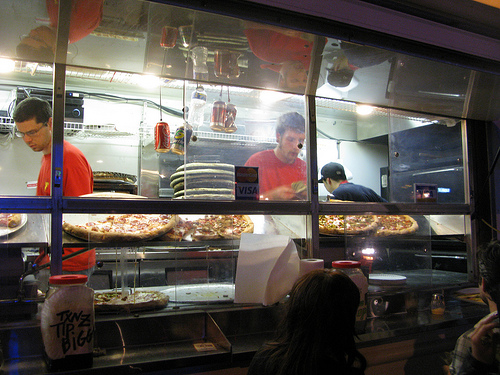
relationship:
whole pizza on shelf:
[63, 191, 180, 245] [0, 213, 467, 247]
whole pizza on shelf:
[161, 215, 254, 242] [0, 213, 467, 247]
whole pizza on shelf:
[318, 213, 383, 236] [0, 213, 467, 247]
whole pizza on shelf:
[375, 215, 419, 235] [0, 213, 467, 247]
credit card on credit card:
[235, 167, 260, 182] [233, 181, 259, 197]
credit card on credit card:
[235, 181, 260, 201] [233, 181, 259, 197]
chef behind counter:
[318, 163, 388, 203] [0, 269, 469, 330]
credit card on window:
[233, 167, 260, 182] [62, 94, 306, 200]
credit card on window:
[233, 181, 259, 197] [62, 94, 306, 200]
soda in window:
[154, 121, 170, 151] [62, 94, 306, 200]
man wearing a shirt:
[12, 98, 95, 294] [35, 141, 97, 271]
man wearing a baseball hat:
[318, 163, 388, 203] [318, 162, 348, 182]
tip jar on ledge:
[40, 275, 95, 371] [0, 338, 230, 374]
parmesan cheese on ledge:
[430, 293, 446, 315] [210, 283, 489, 364]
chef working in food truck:
[318, 163, 388, 203] [0, 1, 498, 373]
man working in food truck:
[12, 98, 95, 294] [0, 1, 498, 373]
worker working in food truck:
[245, 112, 309, 237] [0, 1, 498, 373]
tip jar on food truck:
[40, 275, 95, 371] [0, 1, 498, 373]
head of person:
[280, 268, 359, 344] [246, 267, 368, 374]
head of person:
[479, 242, 500, 301] [442, 239, 499, 374]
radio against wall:
[15, 85, 84, 138] [2, 89, 390, 196]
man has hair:
[12, 98, 95, 294] [13, 97, 52, 126]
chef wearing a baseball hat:
[318, 163, 388, 203] [318, 162, 348, 182]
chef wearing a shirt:
[318, 163, 388, 203] [332, 182, 390, 203]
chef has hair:
[318, 163, 388, 203] [321, 175, 347, 183]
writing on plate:
[50, 310, 93, 352] [42, 286, 96, 360]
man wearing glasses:
[12, 98, 95, 294] [14, 119, 49, 138]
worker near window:
[245, 112, 309, 237] [62, 94, 306, 200]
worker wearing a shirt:
[245, 112, 309, 237] [234, 150, 307, 200]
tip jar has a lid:
[40, 275, 95, 371] [49, 274, 89, 285]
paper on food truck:
[234, 234, 301, 307] [0, 1, 498, 373]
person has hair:
[246, 267, 368, 374] [256, 268, 367, 374]